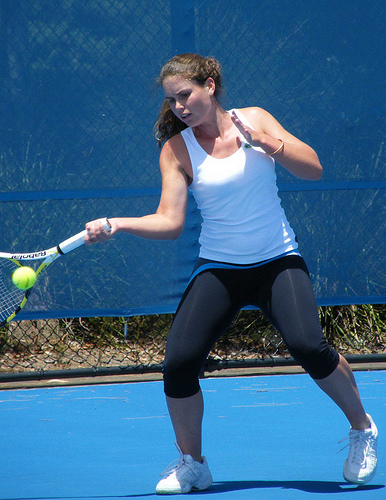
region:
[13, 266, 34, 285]
A GREEN TENNIS BALL.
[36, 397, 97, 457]
THE COURT IS BLUE.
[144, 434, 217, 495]
A WHITE TENNIS SHOE.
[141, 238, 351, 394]
BLACK ATHLETIC PANTS ON THE WOMAN.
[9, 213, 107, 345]
A WHITE TENNIS RACKET.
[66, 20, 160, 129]
A CHAIN LINK FENCE AROUND THE COURT.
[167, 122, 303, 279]
THE WOMAN WEARS A WHITE SHIRT.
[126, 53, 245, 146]
THE WOMAN HAS BLOND HAIR.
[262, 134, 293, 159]
THE WOMAN WEARS A THIN BRACELET.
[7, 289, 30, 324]
A BLACK AND YELLOW TRIM ON THE TENNIS RACKET.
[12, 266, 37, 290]
the tennis ball in the air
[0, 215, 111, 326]
the tennis racquet in the woman's hand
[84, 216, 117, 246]
the hand holding the racquet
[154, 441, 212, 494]
the shoe on the woman's foot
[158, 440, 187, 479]
the laces on the woman's shoe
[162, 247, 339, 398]
the pants on the woman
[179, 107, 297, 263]
the tank top on the woman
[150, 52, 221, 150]
the hair on the woman's head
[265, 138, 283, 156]
the bracelet on the woman's arm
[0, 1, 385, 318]
the blue object on the chain link fence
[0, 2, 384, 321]
blue fabric covering fence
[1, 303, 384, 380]
bottom of chain link fence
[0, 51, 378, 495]
girl playing tennis on court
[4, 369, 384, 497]
blue surface of court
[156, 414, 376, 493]
two white sneakers on feet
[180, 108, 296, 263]
white tank top on body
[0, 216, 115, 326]
hand on tennis racket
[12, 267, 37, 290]
yellow tennis ball in mid air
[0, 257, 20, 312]
white string on racket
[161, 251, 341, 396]
tight black pants on legs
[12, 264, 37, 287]
Tennis ball getting hit.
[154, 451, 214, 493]
Right shoe of tennis player.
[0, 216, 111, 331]
Tennis Racket of tennis player.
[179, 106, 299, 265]
White tank top on tennis player.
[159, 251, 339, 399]
Black latex pants of tennis player.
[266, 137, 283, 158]
Bracelet on tennis players wrist.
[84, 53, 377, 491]
Female playing tennis on court.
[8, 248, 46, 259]
Brand name of tennis racket.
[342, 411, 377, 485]
Left shoe of tennis player.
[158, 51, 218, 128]
Head of the tennis player.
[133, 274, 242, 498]
leg of a woman playing tennis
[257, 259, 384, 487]
leg of a woman playing tennis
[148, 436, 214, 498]
white shoe with white laces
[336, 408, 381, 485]
white shoe with white laces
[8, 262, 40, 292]
bright green tennis ball in the air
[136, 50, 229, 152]
head of a woman playing tennis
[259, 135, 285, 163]
gold bracelet on a wrist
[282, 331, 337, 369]
knee of a woman playing tennis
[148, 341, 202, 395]
knee of a woman playing tennis